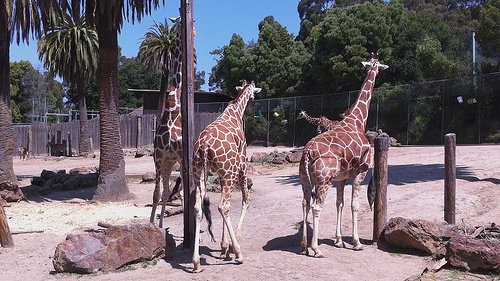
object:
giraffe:
[148, 15, 197, 230]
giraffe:
[189, 80, 261, 274]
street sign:
[258, 109, 263, 118]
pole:
[266, 100, 271, 147]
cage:
[9, 69, 499, 280]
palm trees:
[134, 18, 198, 126]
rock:
[50, 218, 166, 274]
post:
[373, 136, 389, 241]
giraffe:
[299, 52, 389, 259]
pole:
[175, 0, 198, 250]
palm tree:
[0, 3, 148, 203]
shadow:
[23, 169, 99, 199]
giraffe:
[296, 109, 340, 135]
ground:
[7, 147, 497, 277]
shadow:
[260, 219, 371, 256]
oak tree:
[302, 0, 500, 145]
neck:
[347, 72, 379, 127]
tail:
[301, 154, 320, 211]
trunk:
[92, 22, 134, 202]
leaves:
[22, 0, 106, 84]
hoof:
[332, 241, 346, 248]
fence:
[191, 72, 499, 145]